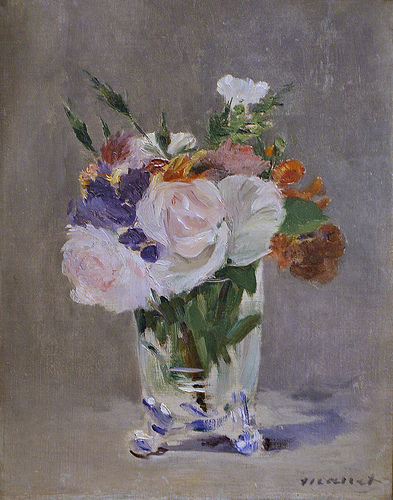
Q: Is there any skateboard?
A: No, there are no skateboards.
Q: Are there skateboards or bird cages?
A: No, there are no skateboards or bird cages.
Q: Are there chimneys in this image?
A: No, there are no chimneys.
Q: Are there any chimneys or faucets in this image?
A: No, there are no chimneys or faucets.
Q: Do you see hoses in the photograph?
A: No, there are no hoses.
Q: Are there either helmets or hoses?
A: No, there are no hoses or helmets.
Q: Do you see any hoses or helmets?
A: No, there are no hoses or helmets.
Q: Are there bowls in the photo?
A: No, there are no bowls.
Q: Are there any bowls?
A: No, there are no bowls.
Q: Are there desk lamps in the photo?
A: No, there are no desk lamps.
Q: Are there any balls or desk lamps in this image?
A: No, there are no desk lamps or balls.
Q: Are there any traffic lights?
A: No, there are no traffic lights.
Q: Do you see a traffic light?
A: No, there are no traffic lights.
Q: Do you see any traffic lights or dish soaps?
A: No, there are no traffic lights or dish soaps.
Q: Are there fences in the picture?
A: No, there are no fences.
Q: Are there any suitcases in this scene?
A: No, there are no suitcases.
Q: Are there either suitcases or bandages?
A: No, there are no suitcases or bandages.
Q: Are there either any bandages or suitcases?
A: No, there are no suitcases or bandages.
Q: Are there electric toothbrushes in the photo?
A: No, there are no electric toothbrushes.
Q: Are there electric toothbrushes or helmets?
A: No, there are no electric toothbrushes or helmets.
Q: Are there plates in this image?
A: No, there are no plates.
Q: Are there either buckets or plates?
A: No, there are no plates or buckets.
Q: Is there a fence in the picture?
A: No, there are no fences.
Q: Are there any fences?
A: No, there are no fences.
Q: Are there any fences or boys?
A: No, there are no fences or boys.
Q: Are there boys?
A: No, there are no boys.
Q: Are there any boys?
A: No, there are no boys.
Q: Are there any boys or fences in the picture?
A: No, there are no boys or fences.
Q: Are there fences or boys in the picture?
A: No, there are no boys or fences.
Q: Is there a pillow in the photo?
A: No, there are no pillows.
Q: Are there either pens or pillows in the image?
A: No, there are no pillows or pens.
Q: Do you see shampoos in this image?
A: No, there are no shampoos.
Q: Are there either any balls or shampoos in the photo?
A: No, there are no shampoos or balls.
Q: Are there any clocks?
A: No, there are no clocks.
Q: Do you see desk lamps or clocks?
A: No, there are no clocks or desk lamps.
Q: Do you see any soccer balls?
A: No, there are no soccer balls.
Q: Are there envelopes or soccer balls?
A: No, there are no soccer balls or envelopes.